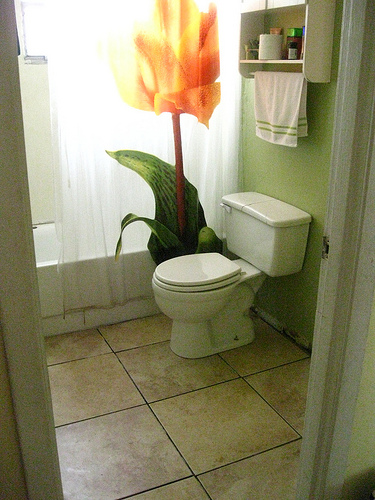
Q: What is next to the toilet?
A: The bathtub.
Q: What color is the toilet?
A: White.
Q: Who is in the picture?
A: Nobody.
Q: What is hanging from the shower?
A: A shower curtain.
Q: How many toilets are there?
A: One.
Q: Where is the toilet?
A: By the wall.